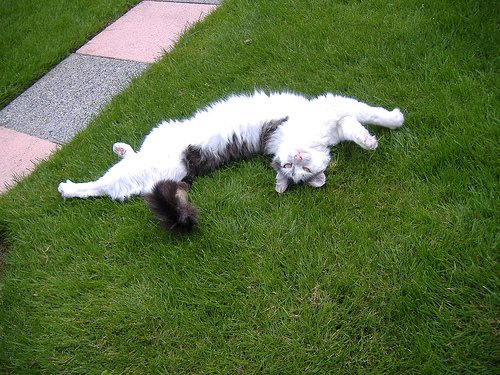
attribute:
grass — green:
[159, 247, 457, 372]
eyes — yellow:
[279, 156, 315, 176]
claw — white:
[390, 98, 411, 138]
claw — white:
[364, 129, 380, 156]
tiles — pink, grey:
[6, 2, 218, 200]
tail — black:
[152, 176, 204, 241]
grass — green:
[224, 218, 493, 372]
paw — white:
[384, 98, 405, 132]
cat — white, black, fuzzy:
[50, 93, 408, 234]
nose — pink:
[290, 147, 311, 168]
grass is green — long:
[412, 35, 497, 123]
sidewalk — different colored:
[42, 55, 132, 122]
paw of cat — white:
[358, 124, 386, 163]